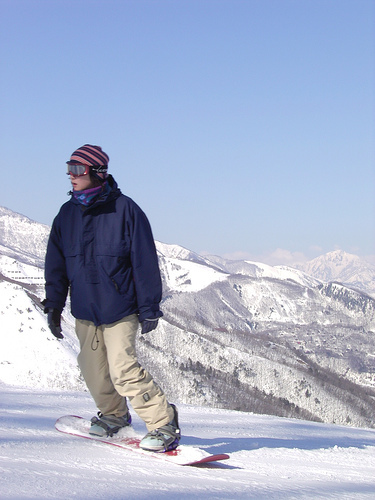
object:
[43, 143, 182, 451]
man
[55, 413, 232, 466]
snowboard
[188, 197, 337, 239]
clouds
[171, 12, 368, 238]
sky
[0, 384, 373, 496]
slope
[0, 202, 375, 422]
hills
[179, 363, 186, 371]
trees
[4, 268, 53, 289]
row of squares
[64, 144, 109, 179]
cap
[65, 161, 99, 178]
goggles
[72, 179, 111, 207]
scarf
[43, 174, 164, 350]
jacket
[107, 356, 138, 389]
knee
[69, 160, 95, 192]
face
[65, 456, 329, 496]
snow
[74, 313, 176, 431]
pants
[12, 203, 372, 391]
landscape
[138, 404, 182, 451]
shoes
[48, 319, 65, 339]
right hand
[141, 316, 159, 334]
left hand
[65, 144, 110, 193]
head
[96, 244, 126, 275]
pocket